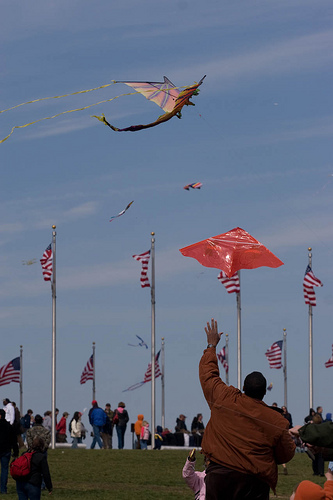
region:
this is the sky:
[28, 15, 102, 49]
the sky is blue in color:
[50, 141, 106, 180]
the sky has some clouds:
[83, 250, 121, 330]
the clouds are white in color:
[77, 264, 143, 316]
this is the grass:
[85, 457, 151, 489]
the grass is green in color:
[79, 452, 135, 472]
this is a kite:
[31, 76, 227, 151]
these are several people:
[2, 385, 332, 499]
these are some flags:
[34, 239, 325, 338]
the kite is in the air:
[93, 78, 222, 141]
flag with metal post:
[37, 229, 61, 468]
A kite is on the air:
[80, 50, 213, 145]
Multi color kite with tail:
[73, 55, 255, 173]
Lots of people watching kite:
[4, 316, 325, 494]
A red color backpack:
[8, 451, 43, 481]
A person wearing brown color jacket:
[200, 345, 294, 482]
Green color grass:
[78, 448, 163, 494]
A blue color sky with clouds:
[21, 57, 304, 224]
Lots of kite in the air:
[24, 39, 286, 367]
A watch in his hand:
[202, 342, 222, 351]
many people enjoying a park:
[14, 338, 331, 489]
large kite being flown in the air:
[19, 55, 236, 164]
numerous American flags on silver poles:
[3, 233, 332, 415]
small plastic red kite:
[188, 219, 282, 285]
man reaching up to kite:
[201, 300, 281, 485]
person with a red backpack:
[9, 448, 37, 490]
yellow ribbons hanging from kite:
[11, 74, 132, 146]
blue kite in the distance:
[125, 331, 153, 357]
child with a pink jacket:
[188, 438, 218, 496]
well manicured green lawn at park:
[88, 456, 140, 488]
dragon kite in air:
[97, 78, 203, 130]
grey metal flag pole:
[51, 231, 55, 445]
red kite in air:
[176, 228, 281, 273]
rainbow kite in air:
[180, 180, 202, 191]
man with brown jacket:
[200, 321, 291, 498]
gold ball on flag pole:
[150, 231, 155, 236]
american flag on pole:
[80, 354, 93, 383]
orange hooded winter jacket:
[134, 414, 144, 436]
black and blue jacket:
[89, 407, 106, 428]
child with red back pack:
[15, 438, 53, 497]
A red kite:
[164, 212, 285, 289]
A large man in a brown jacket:
[191, 317, 294, 493]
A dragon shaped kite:
[85, 72, 211, 140]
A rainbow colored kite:
[182, 177, 204, 194]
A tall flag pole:
[46, 225, 61, 450]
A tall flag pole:
[148, 225, 157, 450]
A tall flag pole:
[306, 244, 314, 407]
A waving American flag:
[36, 235, 54, 283]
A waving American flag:
[74, 353, 93, 387]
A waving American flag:
[132, 245, 151, 290]